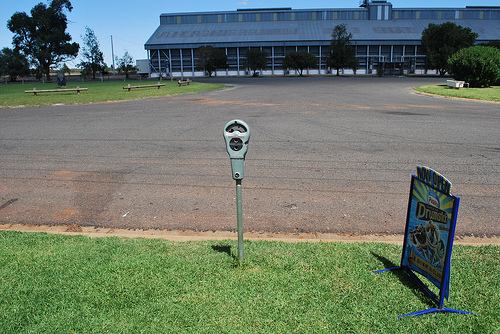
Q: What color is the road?
A: Brown.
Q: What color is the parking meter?
A: Silver.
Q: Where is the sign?
A: By the parking meter.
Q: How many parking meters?
A: One.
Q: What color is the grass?
A: Green.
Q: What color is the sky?
A: Blue.